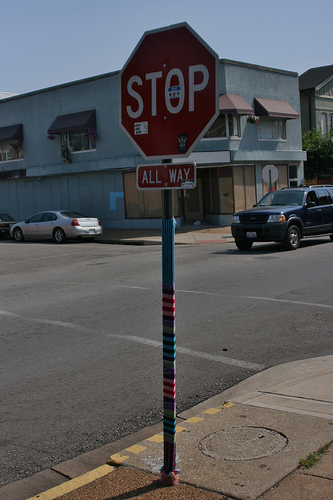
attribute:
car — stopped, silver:
[9, 208, 102, 240]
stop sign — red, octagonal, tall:
[117, 21, 219, 160]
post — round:
[161, 188, 176, 489]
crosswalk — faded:
[0, 280, 327, 371]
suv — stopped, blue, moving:
[231, 184, 333, 258]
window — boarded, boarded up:
[123, 165, 291, 223]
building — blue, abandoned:
[0, 59, 301, 225]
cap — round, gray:
[202, 422, 288, 467]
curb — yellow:
[36, 399, 235, 499]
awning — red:
[258, 98, 299, 124]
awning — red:
[216, 93, 250, 119]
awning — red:
[49, 109, 98, 138]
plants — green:
[56, 142, 70, 165]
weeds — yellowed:
[298, 442, 329, 475]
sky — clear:
[0, 1, 333, 98]